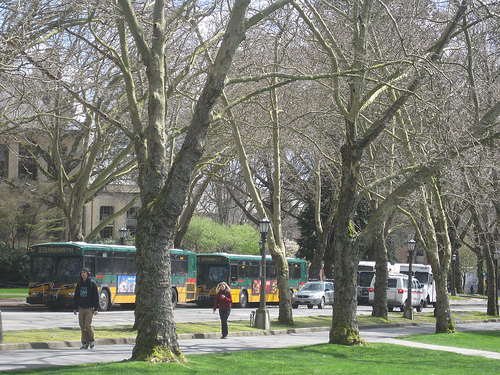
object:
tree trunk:
[128, 191, 188, 364]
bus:
[20, 237, 203, 314]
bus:
[194, 249, 315, 308]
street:
[1, 303, 317, 330]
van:
[343, 256, 396, 306]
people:
[211, 280, 235, 341]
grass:
[297, 349, 416, 375]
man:
[69, 265, 102, 352]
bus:
[350, 258, 398, 305]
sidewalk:
[36, 325, 329, 366]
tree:
[320, 22, 394, 350]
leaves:
[305, 235, 313, 241]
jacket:
[72, 278, 100, 311]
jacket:
[212, 290, 233, 312]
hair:
[215, 281, 232, 294]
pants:
[75, 304, 97, 349]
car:
[289, 280, 338, 310]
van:
[366, 271, 428, 313]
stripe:
[405, 290, 420, 294]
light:
[397, 288, 405, 294]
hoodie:
[84, 274, 94, 285]